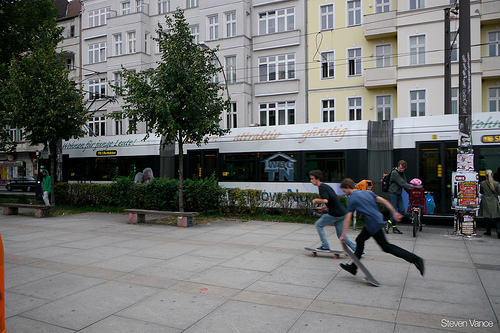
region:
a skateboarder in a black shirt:
[297, 168, 347, 260]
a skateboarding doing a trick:
[335, 179, 432, 291]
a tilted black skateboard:
[340, 231, 379, 287]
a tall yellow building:
[307, 0, 397, 125]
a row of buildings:
[51, 0, 496, 108]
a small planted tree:
[122, 10, 221, 219]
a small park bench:
[125, 207, 197, 224]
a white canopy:
[214, 119, 378, 155]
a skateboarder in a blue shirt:
[330, 175, 429, 295]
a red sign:
[457, 179, 478, 205]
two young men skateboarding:
[302, 170, 426, 287]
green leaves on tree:
[105, 5, 223, 220]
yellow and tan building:
[305, 0, 492, 121]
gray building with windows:
[0, 0, 305, 133]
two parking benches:
[0, 200, 200, 228]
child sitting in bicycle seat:
[407, 177, 424, 234]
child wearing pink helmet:
[405, 177, 425, 236]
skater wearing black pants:
[340, 178, 427, 278]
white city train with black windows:
[5, 111, 499, 223]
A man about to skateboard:
[338, 177, 429, 296]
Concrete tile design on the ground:
[50, 241, 218, 322]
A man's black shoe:
[338, 260, 351, 272]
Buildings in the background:
[236, 11, 415, 106]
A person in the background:
[383, 162, 425, 193]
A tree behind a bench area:
[128, 40, 215, 237]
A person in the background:
[40, 169, 53, 206]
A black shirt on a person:
[318, 182, 338, 214]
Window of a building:
[321, 52, 337, 80]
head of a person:
[337, 173, 366, 195]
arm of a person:
[325, 211, 360, 246]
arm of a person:
[373, 193, 405, 218]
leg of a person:
[352, 224, 377, 271]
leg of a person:
[366, 224, 422, 268]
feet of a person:
[328, 260, 370, 285]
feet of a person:
[410, 253, 432, 283]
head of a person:
[300, 164, 326, 184]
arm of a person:
[310, 195, 327, 205]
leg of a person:
[303, 217, 340, 248]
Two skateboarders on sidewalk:
[299, 167, 427, 288]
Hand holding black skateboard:
[337, 237, 382, 289]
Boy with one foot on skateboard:
[300, 169, 343, 259]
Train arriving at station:
[0, 110, 498, 218]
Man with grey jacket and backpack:
[376, 156, 406, 196]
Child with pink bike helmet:
[407, 175, 427, 235]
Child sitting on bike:
[405, 176, 425, 236]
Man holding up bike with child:
[377, 151, 427, 232]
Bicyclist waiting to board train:
[405, 130, 466, 237]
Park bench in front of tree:
[122, 199, 197, 231]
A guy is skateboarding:
[295, 161, 372, 266]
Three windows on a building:
[315, 35, 400, 86]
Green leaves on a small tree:
[101, 0, 237, 215]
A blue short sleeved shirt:
[335, 182, 392, 237]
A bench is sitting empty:
[115, 197, 200, 232]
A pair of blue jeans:
[310, 205, 360, 251]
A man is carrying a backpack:
[371, 151, 416, 197]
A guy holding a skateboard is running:
[326, 170, 428, 287]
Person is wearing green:
[31, 160, 53, 195]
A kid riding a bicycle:
[400, 171, 436, 243]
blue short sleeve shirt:
[345, 190, 386, 231]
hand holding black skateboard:
[337, 231, 378, 288]